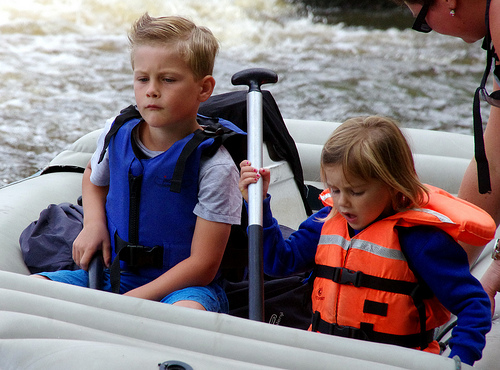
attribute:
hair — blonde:
[126, 11, 217, 80]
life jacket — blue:
[103, 105, 245, 285]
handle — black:
[230, 102, 272, 219]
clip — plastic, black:
[330, 265, 362, 289]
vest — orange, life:
[319, 212, 427, 334]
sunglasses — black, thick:
[315, 162, 397, 223]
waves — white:
[290, 24, 472, 116]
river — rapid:
[11, 5, 470, 189]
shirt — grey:
[87, 130, 244, 283]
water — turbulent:
[0, 3, 494, 188]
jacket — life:
[91, 105, 247, 287]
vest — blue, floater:
[94, 109, 248, 280]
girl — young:
[232, 105, 499, 341]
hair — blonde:
[289, 106, 434, 231]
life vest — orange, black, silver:
[309, 187, 459, 355]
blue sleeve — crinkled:
[405, 223, 497, 368]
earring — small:
[446, 7, 459, 18]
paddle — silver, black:
[209, 50, 290, 345]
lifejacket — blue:
[97, 116, 223, 285]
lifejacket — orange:
[280, 179, 482, 346]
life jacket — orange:
[331, 215, 450, 322]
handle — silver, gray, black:
[229, 65, 280, 93]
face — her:
[419, 0, 464, 30]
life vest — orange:
[299, 172, 494, 350]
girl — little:
[205, 109, 498, 370]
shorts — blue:
[39, 264, 228, 313]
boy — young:
[27, 12, 244, 313]